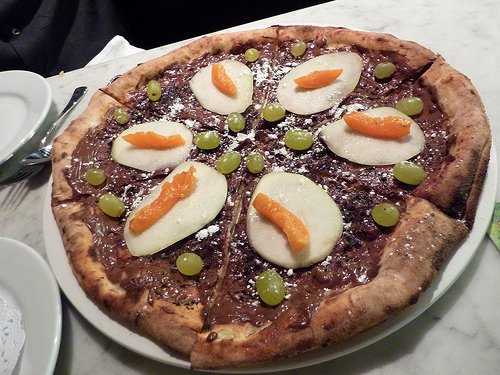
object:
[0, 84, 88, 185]
fork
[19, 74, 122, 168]
spoon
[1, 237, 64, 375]
plate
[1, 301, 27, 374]
doily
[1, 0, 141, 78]
shirt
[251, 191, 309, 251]
orange puree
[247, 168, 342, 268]
white slice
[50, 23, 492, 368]
pizza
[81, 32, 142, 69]
napkin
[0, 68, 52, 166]
plate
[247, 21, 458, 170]
slice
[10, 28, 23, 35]
button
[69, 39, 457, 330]
sauce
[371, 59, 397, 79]
grape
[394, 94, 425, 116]
grape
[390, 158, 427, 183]
grape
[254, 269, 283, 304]
grape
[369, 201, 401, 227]
grape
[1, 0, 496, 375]
table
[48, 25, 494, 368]
crust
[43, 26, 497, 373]
plate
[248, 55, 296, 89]
white powder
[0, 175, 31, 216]
shadow